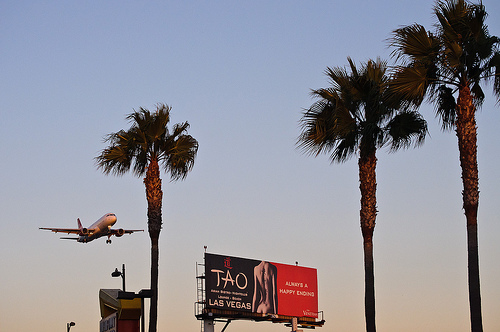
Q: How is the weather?
A: It is clear.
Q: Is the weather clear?
A: Yes, it is clear.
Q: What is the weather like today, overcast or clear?
A: It is clear.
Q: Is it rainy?
A: No, it is clear.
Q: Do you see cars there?
A: No, there are no cars.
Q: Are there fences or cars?
A: No, there are no cars or fences.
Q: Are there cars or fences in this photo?
A: No, there are no cars or fences.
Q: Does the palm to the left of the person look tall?
A: Yes, the palm is tall.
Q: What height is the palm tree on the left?
A: The palm is tall.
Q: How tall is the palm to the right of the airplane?
A: The palm is tall.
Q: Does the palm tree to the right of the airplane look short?
A: No, the palm tree is tall.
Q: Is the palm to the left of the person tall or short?
A: The palm is tall.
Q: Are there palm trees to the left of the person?
A: Yes, there is a palm tree to the left of the person.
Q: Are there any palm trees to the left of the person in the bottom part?
A: Yes, there is a palm tree to the left of the person.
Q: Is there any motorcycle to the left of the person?
A: No, there is a palm tree to the left of the person.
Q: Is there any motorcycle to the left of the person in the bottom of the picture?
A: No, there is a palm tree to the left of the person.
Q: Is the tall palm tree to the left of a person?
A: Yes, the palm tree is to the left of a person.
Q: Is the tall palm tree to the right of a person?
A: No, the palm tree is to the left of a person.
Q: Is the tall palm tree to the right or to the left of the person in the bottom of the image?
A: The palm tree is to the left of the person.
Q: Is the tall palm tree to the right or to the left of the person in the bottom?
A: The palm tree is to the left of the person.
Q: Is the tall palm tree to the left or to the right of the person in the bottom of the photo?
A: The palm tree is to the left of the person.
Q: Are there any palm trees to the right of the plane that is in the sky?
A: Yes, there is a palm tree to the right of the airplane.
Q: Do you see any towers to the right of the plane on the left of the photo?
A: No, there is a palm tree to the right of the plane.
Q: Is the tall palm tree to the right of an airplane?
A: Yes, the palm is to the right of an airplane.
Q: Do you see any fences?
A: No, there are no fences.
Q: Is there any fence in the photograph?
A: No, there are no fences.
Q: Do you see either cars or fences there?
A: No, there are no fences or cars.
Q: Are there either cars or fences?
A: No, there are no fences or cars.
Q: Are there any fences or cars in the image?
A: No, there are no fences or cars.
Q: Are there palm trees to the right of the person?
A: Yes, there is a palm tree to the right of the person.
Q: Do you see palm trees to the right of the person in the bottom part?
A: Yes, there is a palm tree to the right of the person.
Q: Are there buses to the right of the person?
A: No, there is a palm tree to the right of the person.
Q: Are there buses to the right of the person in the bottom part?
A: No, there is a palm tree to the right of the person.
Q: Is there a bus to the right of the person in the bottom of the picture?
A: No, there is a palm tree to the right of the person.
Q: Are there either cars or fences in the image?
A: No, there are no cars or fences.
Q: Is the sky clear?
A: Yes, the sky is clear.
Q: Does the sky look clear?
A: Yes, the sky is clear.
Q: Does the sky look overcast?
A: No, the sky is clear.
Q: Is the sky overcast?
A: No, the sky is clear.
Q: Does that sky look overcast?
A: No, the sky is clear.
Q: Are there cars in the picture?
A: No, there are no cars.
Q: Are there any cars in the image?
A: No, there are no cars.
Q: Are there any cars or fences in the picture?
A: No, there are no cars or fences.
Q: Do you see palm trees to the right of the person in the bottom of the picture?
A: Yes, there are palm trees to the right of the person.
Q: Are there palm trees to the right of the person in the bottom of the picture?
A: Yes, there are palm trees to the right of the person.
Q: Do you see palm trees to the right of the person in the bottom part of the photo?
A: Yes, there are palm trees to the right of the person.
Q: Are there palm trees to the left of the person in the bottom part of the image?
A: No, the palm trees are to the right of the person.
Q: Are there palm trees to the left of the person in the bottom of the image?
A: No, the palm trees are to the right of the person.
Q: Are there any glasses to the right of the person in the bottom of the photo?
A: No, there are palm trees to the right of the person.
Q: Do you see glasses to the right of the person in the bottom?
A: No, there are palm trees to the right of the person.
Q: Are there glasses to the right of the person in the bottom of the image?
A: No, there are palm trees to the right of the person.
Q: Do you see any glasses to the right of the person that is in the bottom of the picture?
A: No, there are palm trees to the right of the person.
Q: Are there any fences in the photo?
A: No, there are no fences.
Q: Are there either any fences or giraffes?
A: No, there are no fences or giraffes.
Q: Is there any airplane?
A: Yes, there is an airplane.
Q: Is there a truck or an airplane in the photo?
A: Yes, there is an airplane.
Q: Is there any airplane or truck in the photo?
A: Yes, there is an airplane.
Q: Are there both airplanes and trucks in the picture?
A: No, there is an airplane but no trucks.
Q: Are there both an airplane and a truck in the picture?
A: No, there is an airplane but no trucks.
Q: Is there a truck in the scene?
A: No, there are no trucks.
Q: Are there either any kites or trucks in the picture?
A: No, there are no trucks or kites.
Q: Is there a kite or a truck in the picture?
A: No, there are no trucks or kites.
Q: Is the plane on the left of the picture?
A: Yes, the plane is on the left of the image.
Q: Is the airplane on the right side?
A: No, the airplane is on the left of the image.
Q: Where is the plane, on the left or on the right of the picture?
A: The plane is on the left of the image.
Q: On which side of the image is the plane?
A: The plane is on the left of the image.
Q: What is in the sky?
A: The plane is in the sky.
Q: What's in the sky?
A: The plane is in the sky.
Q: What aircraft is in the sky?
A: The aircraft is an airplane.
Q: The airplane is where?
A: The airplane is in the sky.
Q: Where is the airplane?
A: The airplane is in the sky.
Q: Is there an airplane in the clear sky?
A: Yes, there is an airplane in the sky.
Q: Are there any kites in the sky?
A: No, there is an airplane in the sky.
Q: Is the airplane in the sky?
A: Yes, the airplane is in the sky.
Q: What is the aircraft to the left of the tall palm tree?
A: The aircraft is an airplane.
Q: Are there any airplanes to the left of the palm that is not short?
A: Yes, there is an airplane to the left of the palm tree.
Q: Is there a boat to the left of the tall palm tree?
A: No, there is an airplane to the left of the palm tree.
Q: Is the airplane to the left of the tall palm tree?
A: Yes, the airplane is to the left of the palm tree.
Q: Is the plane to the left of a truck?
A: No, the plane is to the left of the palm tree.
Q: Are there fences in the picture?
A: No, there are no fences.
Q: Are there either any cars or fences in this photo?
A: No, there are no fences or cars.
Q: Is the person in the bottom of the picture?
A: Yes, the person is in the bottom of the image.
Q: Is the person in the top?
A: No, the person is in the bottom of the image.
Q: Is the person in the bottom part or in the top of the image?
A: The person is in the bottom of the image.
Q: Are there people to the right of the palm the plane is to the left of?
A: Yes, there is a person to the right of the palm tree.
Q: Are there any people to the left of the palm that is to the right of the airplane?
A: No, the person is to the right of the palm tree.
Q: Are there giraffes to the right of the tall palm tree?
A: No, there is a person to the right of the palm.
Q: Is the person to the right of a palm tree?
A: Yes, the person is to the right of a palm tree.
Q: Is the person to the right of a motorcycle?
A: No, the person is to the right of a palm tree.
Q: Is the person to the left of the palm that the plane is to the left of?
A: No, the person is to the right of the palm.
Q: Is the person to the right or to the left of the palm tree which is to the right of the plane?
A: The person is to the right of the palm tree.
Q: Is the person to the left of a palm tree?
A: Yes, the person is to the left of a palm tree.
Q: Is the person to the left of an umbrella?
A: No, the person is to the left of a palm tree.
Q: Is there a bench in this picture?
A: No, there are no benches.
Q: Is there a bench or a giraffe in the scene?
A: No, there are no benches or giraffes.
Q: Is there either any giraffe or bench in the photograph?
A: No, there are no benches or giraffes.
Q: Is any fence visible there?
A: No, there are no fences.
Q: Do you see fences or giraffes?
A: No, there are no fences or giraffes.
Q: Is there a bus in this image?
A: No, there are no buses.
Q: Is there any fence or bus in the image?
A: No, there are no buses or fences.